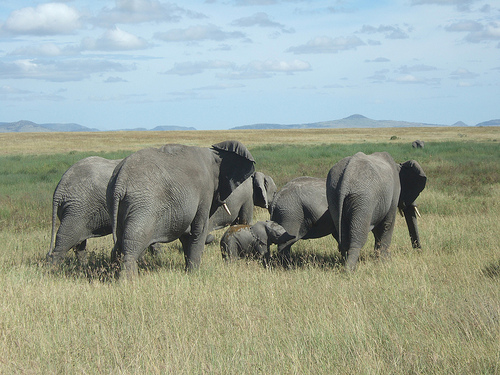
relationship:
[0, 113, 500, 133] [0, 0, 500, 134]
mountains are in distance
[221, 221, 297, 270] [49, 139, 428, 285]
elephant in a herd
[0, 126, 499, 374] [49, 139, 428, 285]
field has elephants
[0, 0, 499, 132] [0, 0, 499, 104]
sky has clouds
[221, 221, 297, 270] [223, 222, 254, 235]
baby elephant colored brown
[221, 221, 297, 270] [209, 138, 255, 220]
elephant has an ear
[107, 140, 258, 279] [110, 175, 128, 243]
elephant has a tail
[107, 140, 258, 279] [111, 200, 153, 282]
elephant has a back leg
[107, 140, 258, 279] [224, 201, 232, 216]
elephant has a tusk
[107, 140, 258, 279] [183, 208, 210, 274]
elephant has a front leg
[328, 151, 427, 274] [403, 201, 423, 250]
elephant has a trunk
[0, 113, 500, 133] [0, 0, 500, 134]
hills are in distance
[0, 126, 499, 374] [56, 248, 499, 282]
grass has shadows